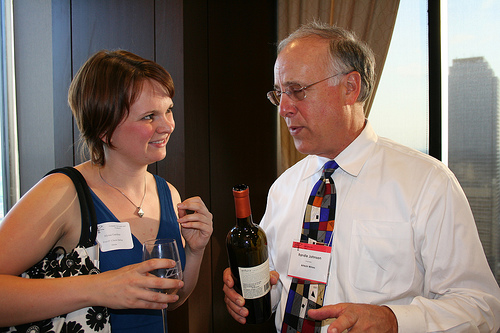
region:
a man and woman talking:
[16, 30, 457, 327]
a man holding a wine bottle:
[210, 39, 396, 326]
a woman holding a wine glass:
[99, 53, 229, 328]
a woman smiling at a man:
[48, 37, 190, 194]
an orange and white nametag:
[271, 242, 334, 292]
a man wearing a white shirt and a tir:
[255, 41, 447, 324]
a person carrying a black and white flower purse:
[0, 143, 114, 331]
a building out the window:
[443, 37, 499, 302]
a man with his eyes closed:
[248, 53, 365, 155]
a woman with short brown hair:
[59, 44, 170, 201]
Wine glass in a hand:
[138, 227, 184, 326]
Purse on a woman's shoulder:
[13, 160, 127, 330]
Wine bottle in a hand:
[213, 167, 286, 327]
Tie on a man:
[293, 139, 355, 329]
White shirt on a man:
[221, 116, 493, 331]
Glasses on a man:
[246, 18, 343, 229]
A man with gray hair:
[259, 5, 419, 141]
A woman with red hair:
[50, 30, 184, 176]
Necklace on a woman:
[88, 153, 178, 253]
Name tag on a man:
[278, 236, 356, 305]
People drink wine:
[16, 24, 486, 328]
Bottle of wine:
[213, 174, 280, 330]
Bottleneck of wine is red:
[216, 174, 285, 327]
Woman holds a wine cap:
[0, 39, 221, 329]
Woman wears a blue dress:
[6, 46, 222, 331]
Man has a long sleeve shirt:
[209, 7, 499, 332]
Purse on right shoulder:
[3, 160, 118, 332]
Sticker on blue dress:
[89, 215, 136, 255]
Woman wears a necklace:
[37, 44, 202, 235]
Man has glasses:
[239, 16, 424, 203]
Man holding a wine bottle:
[220, 20, 496, 330]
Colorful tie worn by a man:
[280, 160, 336, 330]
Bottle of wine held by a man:
[225, 183, 271, 326]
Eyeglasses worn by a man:
[263, 66, 358, 107]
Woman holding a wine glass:
[0, 48, 215, 329]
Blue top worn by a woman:
[61, 162, 186, 328]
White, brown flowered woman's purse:
[2, 166, 107, 331]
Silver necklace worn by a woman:
[96, 161, 151, 217]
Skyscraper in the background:
[442, 50, 499, 267]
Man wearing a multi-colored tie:
[288, 162, 327, 332]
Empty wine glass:
[140, 237, 185, 332]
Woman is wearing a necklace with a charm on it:
[68, 52, 177, 219]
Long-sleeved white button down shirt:
[281, 154, 490, 331]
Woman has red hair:
[67, 45, 179, 168]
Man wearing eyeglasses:
[266, 82, 317, 101]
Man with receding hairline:
[253, 25, 370, 87]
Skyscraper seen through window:
[446, 53, 499, 243]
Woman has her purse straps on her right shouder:
[9, 164, 116, 331]